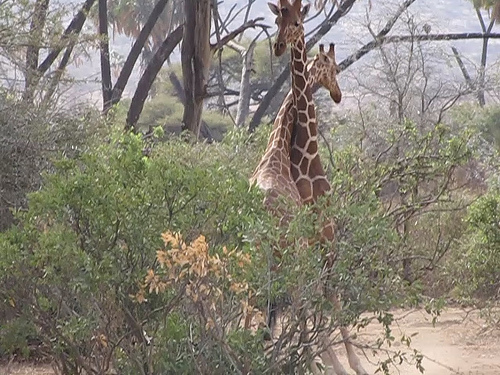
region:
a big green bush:
[100, 142, 330, 289]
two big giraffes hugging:
[251, 23, 395, 162]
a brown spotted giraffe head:
[303, 40, 370, 100]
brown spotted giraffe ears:
[311, 30, 364, 67]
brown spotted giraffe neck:
[253, 41, 321, 182]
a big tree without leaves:
[143, 10, 276, 125]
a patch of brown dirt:
[372, 282, 489, 362]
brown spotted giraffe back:
[226, 102, 306, 206]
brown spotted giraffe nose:
[265, 29, 300, 76]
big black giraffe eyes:
[256, 10, 331, 35]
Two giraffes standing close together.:
[223, 1, 373, 311]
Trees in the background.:
[13, 0, 490, 135]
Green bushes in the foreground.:
[14, 120, 484, 370]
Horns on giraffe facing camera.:
[260, 1, 313, 52]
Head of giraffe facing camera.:
[262, 2, 317, 57]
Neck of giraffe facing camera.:
[286, 40, 326, 184]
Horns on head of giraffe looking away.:
[311, 33, 353, 104]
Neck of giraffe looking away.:
[270, 68, 311, 166]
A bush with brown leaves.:
[127, 221, 265, 345]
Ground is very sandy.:
[262, 301, 496, 368]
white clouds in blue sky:
[363, 54, 389, 92]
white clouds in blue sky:
[353, 13, 393, 48]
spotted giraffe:
[256, 10, 347, 210]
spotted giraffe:
[275, 7, 312, 104]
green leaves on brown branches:
[30, 140, 81, 232]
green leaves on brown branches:
[92, 150, 162, 205]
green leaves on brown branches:
[37, 235, 127, 295]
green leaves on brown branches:
[157, 153, 207, 204]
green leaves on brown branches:
[357, 130, 427, 190]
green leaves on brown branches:
[393, 187, 450, 250]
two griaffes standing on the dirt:
[247, 4, 390, 372]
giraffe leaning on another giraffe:
[237, 1, 377, 373]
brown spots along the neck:
[285, 44, 336, 197]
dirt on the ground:
[287, 305, 498, 372]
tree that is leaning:
[319, 9, 497, 92]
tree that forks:
[97, 1, 174, 115]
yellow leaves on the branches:
[134, 225, 275, 335]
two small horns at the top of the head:
[316, 38, 333, 52]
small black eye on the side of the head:
[291, 20, 303, 29]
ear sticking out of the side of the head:
[265, 1, 283, 13]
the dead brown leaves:
[137, 238, 269, 332]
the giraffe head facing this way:
[267, 2, 307, 47]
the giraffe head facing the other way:
[310, 46, 355, 101]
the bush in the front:
[15, 140, 405, 372]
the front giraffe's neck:
[290, 40, 312, 170]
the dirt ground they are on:
[15, 290, 496, 365]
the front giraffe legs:
[326, 272, 366, 367]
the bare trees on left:
[40, 19, 237, 112]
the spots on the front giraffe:
[290, 45, 342, 245]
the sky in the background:
[7, 20, 493, 107]